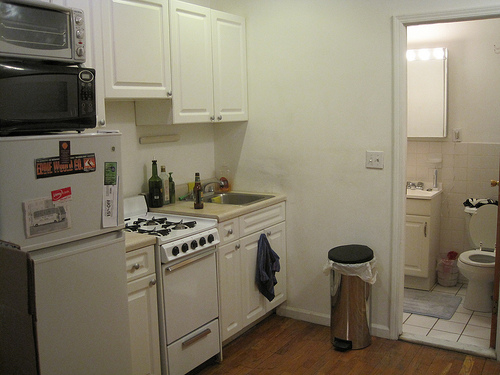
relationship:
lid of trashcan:
[330, 244, 375, 264] [327, 244, 375, 352]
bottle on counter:
[193, 172, 204, 209] [150, 191, 288, 223]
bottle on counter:
[150, 159, 163, 207] [150, 191, 288, 223]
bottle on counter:
[160, 164, 171, 207] [150, 191, 288, 223]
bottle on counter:
[166, 171, 176, 204] [150, 191, 288, 223]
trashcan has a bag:
[327, 244, 375, 352] [324, 259, 379, 285]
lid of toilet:
[469, 203, 500, 250] [458, 203, 499, 313]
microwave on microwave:
[1, 0, 87, 68] [1, 62, 97, 136]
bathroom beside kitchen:
[406, 20, 499, 347] [1, 0, 395, 374]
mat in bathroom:
[403, 289, 462, 323] [406, 20, 499, 347]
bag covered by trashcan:
[324, 259, 379, 285] [327, 244, 375, 352]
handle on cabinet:
[423, 221, 429, 239] [407, 188, 443, 293]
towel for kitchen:
[257, 234, 280, 302] [1, 0, 395, 374]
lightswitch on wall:
[367, 149, 386, 171] [214, 0, 402, 337]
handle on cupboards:
[167, 88, 174, 97] [102, 0, 171, 100]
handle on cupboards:
[210, 113, 218, 121] [136, 0, 249, 125]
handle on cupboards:
[216, 115, 227, 122] [136, 0, 249, 125]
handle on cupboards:
[148, 276, 158, 287] [129, 273, 161, 374]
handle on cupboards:
[235, 241, 243, 250] [216, 236, 245, 347]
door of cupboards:
[214, 10, 248, 122] [136, 0, 249, 125]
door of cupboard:
[268, 223, 291, 311] [245, 219, 286, 327]